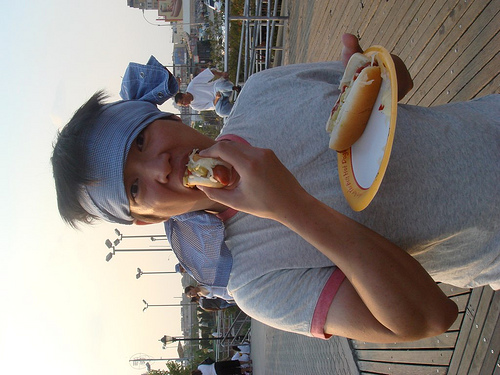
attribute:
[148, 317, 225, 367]
lamp — black, streetlamp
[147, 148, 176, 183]
nose — little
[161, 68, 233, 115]
man — sitting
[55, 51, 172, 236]
bandana — blue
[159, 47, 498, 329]
shirt — grey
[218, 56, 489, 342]
t-shirt — white, grey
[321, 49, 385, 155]
bun — brown, white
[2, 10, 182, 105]
clouds — white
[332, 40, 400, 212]
plate — paper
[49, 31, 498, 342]
man — standing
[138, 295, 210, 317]
pole — metal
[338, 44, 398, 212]
plate — yellow, red words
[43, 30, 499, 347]
person — wearing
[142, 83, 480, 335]
shirt — red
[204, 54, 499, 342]
shirt — grey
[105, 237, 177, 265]
light — tall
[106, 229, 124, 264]
street — tall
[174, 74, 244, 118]
person — sitting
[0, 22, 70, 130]
sky — clear, blue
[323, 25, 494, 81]
decking — wood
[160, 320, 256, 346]
post — electric